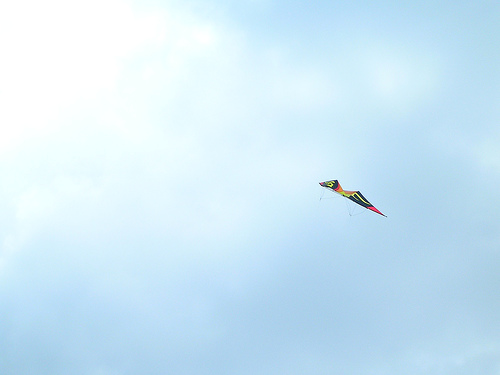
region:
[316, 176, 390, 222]
A multi colored kite in the sky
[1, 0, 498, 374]
A clear blue sky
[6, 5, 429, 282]
some clouds in the sky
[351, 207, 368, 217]
A support string on the kite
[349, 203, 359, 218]
A support string on the kite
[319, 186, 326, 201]
some support strings on the kite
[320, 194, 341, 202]
A support string on the kite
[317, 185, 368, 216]
support strings on the kite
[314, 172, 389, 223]
A kite in the sky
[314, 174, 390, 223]
A red, blue, yellow, and orange kite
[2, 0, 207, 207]
a white cloud in the sky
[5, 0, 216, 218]
a white cloud in the blue sky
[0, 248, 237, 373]
the clear blue sky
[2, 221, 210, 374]
the blue sky with minimal clouds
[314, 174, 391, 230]
a hang glider in the sky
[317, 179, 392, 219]
a hang glider in the blue sky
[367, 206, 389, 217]
a hang glider with a red tipped wing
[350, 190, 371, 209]
a hang glider with a black and white wing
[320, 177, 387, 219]
a hanglider that is red, black, white, orange, and green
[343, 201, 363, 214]
the strings of the hang glider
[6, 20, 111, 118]
The sky is white here.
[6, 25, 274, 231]
The sky is partly cloudy.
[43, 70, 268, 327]
The sky is partly clear.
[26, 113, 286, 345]
Part of the sky looks hazy.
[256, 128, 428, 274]
This is a kite.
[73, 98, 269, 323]
The weather looks nice.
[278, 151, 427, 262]
The kit is flying with wind.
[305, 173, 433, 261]
The kite is multicolored.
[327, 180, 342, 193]
Part of the kite is red.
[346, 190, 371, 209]
Part of the kite is black and yellow.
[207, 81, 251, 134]
part of a cloud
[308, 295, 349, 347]
part of the sky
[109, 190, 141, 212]
part of a cloud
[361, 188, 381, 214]
part of a plane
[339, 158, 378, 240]
part of a plane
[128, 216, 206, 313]
part of a cloud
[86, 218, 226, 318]
Sky is blue color.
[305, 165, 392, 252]
Kite is flying in air.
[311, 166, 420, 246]
Kite is red and black color.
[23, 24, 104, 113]
Sun is shining brightly.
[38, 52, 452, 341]
Day time picture.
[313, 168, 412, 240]
White lines in kite.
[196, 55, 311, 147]
Clouds are white color.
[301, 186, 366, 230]
Thread of kite is seen.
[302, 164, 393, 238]
Kite is hig in sky.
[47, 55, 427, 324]
Out door picture.